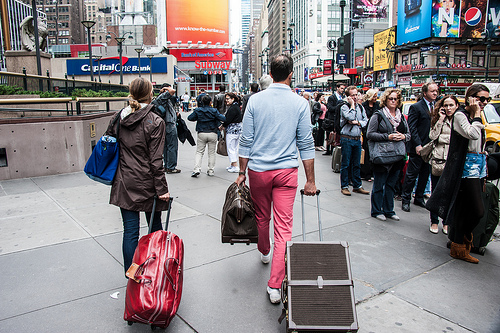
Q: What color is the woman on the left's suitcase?
A: Red.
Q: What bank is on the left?
A: Capitol One Bank.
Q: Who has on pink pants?
A: Man with light blue shirt.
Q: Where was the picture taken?
A: City.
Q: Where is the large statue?
A: Left side.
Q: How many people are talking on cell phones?
A: Three.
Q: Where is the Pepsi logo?
A: Right.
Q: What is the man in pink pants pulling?
A: Luggage.